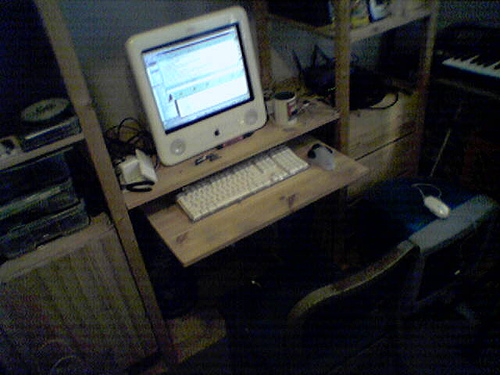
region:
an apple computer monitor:
[83, 1, 354, 176]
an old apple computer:
[94, 9, 353, 182]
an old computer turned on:
[99, 33, 319, 140]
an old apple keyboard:
[140, 162, 358, 224]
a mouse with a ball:
[278, 126, 370, 192]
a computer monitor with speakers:
[106, 22, 297, 160]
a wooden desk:
[24, 25, 457, 180]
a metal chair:
[177, 224, 452, 356]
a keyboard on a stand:
[433, 12, 498, 118]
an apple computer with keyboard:
[83, 18, 355, 228]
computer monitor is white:
[125, 2, 271, 167]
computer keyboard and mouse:
[175, 136, 340, 216]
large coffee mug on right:
[266, 85, 296, 130]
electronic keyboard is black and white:
[425, 26, 495, 83]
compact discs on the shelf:
[6, 92, 72, 147]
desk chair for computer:
[246, 226, 421, 371]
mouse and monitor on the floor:
[410, 175, 496, 315]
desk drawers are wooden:
[350, 86, 420, 186]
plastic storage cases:
[0, 155, 105, 255]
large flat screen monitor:
[116, 7, 291, 171]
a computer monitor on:
[88, 8, 303, 170]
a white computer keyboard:
[161, 127, 313, 257]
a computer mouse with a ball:
[277, 115, 377, 192]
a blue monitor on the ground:
[340, 180, 499, 307]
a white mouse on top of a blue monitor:
[393, 169, 465, 235]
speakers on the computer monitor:
[154, 115, 316, 149]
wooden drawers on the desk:
[307, 65, 443, 203]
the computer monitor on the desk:
[127, 2, 276, 155]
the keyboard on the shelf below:
[183, 143, 310, 218]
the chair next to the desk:
[255, 238, 434, 361]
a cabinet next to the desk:
[1, 263, 158, 362]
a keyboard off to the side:
[439, 20, 497, 91]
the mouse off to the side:
[402, 166, 452, 228]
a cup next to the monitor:
[272, 90, 297, 129]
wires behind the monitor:
[108, 111, 166, 190]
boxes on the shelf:
[13, 176, 93, 260]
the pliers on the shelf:
[122, 177, 157, 196]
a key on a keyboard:
[188, 202, 203, 219]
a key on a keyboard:
[179, 195, 189, 207]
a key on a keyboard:
[207, 202, 218, 218]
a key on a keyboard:
[191, 196, 198, 206]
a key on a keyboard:
[191, 203, 198, 210]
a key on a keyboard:
[287, 163, 295, 173]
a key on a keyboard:
[271, 170, 281, 182]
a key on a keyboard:
[247, 175, 254, 185]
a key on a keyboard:
[222, 180, 230, 187]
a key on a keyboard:
[206, 187, 216, 195]